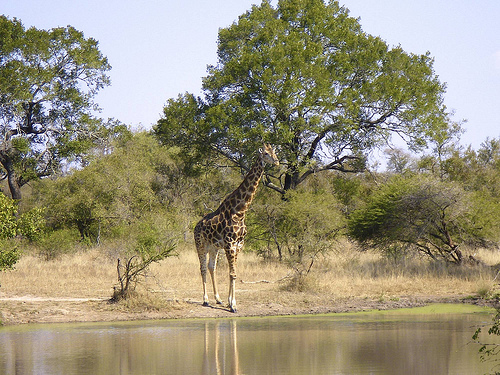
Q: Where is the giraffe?
A: By the water.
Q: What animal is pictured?
A: A giraffe.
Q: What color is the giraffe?
A: Brown.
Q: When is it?
A: Day time.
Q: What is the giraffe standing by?
A: The water.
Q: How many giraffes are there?
A: One.